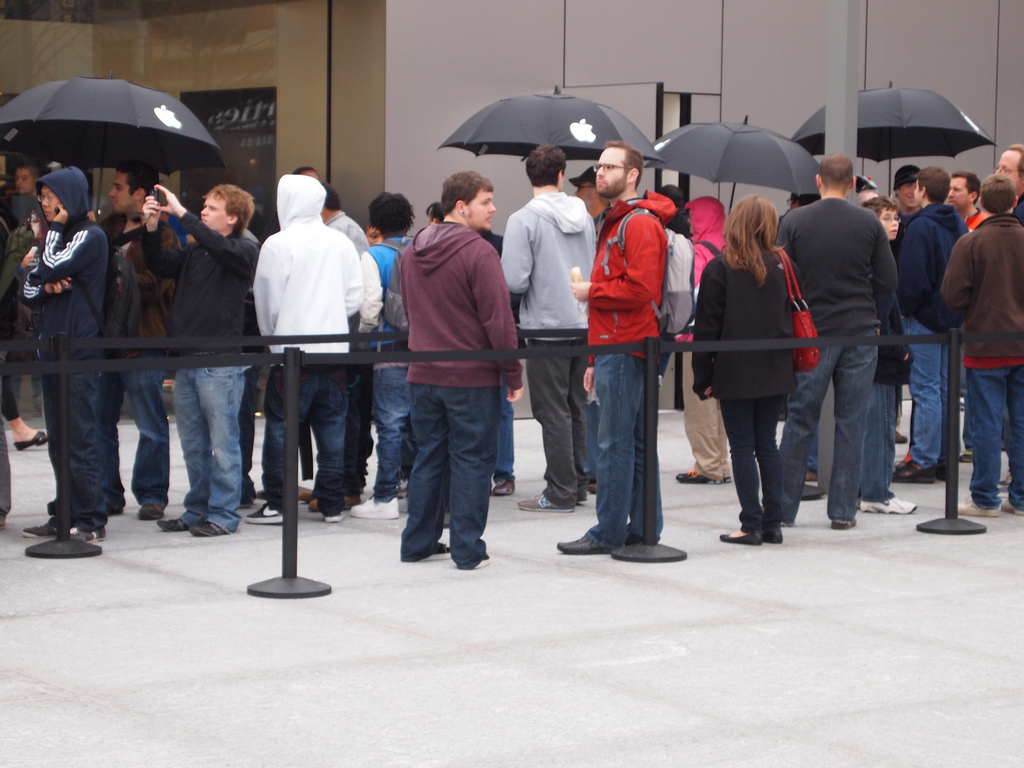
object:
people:
[18, 166, 107, 544]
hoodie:
[401, 223, 525, 390]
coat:
[587, 189, 677, 368]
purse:
[775, 247, 820, 372]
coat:
[691, 244, 802, 398]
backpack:
[602, 206, 696, 340]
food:
[570, 266, 584, 283]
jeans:
[585, 351, 664, 551]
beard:
[596, 174, 626, 199]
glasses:
[593, 163, 633, 172]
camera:
[149, 187, 159, 211]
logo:
[569, 118, 597, 143]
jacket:
[252, 173, 366, 354]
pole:
[823, 1, 860, 206]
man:
[555, 139, 667, 554]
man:
[139, 183, 258, 539]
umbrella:
[438, 85, 666, 162]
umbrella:
[0, 67, 227, 220]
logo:
[153, 104, 182, 129]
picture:
[0, 0, 1022, 766]